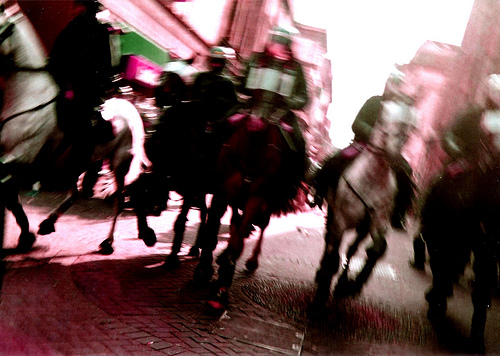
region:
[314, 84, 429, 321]
this is a horse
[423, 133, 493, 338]
this is a horse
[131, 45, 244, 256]
this is a horse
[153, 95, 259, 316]
this is a horse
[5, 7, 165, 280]
this is a horse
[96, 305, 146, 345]
these are blocks on the ground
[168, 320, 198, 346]
these are blocks on the ground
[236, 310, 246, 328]
these are blocks on the ground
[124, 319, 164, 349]
these are blocks on the ground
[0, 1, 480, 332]
people on horses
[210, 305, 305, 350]
square in the middle of the gournd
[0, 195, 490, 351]
bricked streets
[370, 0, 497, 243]
buildings on the right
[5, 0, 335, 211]
buildings on the right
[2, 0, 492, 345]
blurry because in motion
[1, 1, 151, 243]
rider on a white horse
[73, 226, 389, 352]
a circle on the ground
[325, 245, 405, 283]
square grate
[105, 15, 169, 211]
a stand or store on the left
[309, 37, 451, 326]
A person on a horse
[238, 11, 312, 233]
A person on a horse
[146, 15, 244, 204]
A person on a horse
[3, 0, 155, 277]
A person on a horse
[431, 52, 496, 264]
A person on a horse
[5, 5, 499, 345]
Blurry people riding on horses in a street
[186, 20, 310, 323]
person with a hat riding a dark horse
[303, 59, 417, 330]
someone riding a light color horse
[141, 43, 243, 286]
man wearing a green helmet on horse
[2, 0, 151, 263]
a white horse with a rider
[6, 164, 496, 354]
red brick road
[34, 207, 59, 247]
hoof of a horse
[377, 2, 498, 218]
buildings on the side of a street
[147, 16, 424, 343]
three riders on horses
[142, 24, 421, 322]
three riders in the middle of a small street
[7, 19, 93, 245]
horse galloping down brick road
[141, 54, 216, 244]
horse galloping down brick road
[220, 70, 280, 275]
horse galloping down brick road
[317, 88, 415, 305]
horse galloping down brick road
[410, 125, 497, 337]
horse galloping down brick road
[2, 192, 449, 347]
brick road below horses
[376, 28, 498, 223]
tall buildings on right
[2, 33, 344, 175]
tall buildings on left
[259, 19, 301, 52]
helmet on horse jockey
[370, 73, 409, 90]
helmet on horse jockey